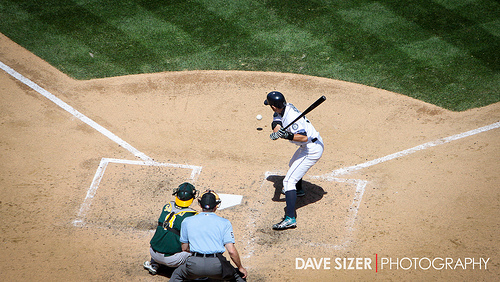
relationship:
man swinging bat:
[264, 89, 327, 231] [270, 96, 328, 139]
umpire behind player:
[168, 187, 249, 281] [143, 183, 199, 276]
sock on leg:
[285, 188, 299, 218] [282, 143, 324, 217]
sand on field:
[2, 30, 500, 281] [0, 0, 499, 281]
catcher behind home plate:
[143, 183, 199, 276] [216, 193, 243, 213]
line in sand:
[0, 59, 152, 168] [2, 30, 500, 281]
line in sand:
[319, 121, 499, 180] [2, 30, 500, 281]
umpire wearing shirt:
[168, 187, 249, 281] [179, 210, 236, 254]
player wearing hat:
[143, 183, 199, 276] [175, 183, 195, 207]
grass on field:
[0, 0, 499, 112] [0, 0, 499, 281]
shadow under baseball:
[256, 127, 266, 132] [256, 114, 263, 121]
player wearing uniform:
[143, 183, 199, 276] [151, 200, 194, 266]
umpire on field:
[168, 187, 249, 281] [0, 0, 499, 281]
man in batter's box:
[264, 89, 327, 231] [73, 156, 368, 259]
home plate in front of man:
[216, 193, 243, 213] [264, 89, 327, 231]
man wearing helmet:
[264, 89, 327, 231] [263, 90, 286, 107]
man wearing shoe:
[264, 89, 327, 231] [272, 215, 298, 231]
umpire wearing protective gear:
[168, 187, 249, 281] [198, 189, 221, 208]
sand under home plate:
[2, 30, 500, 281] [216, 193, 243, 213]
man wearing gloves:
[264, 89, 327, 231] [270, 128, 290, 142]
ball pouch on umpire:
[215, 253, 237, 279] [168, 187, 249, 281]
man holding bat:
[264, 89, 327, 231] [270, 96, 328, 139]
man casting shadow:
[264, 89, 327, 231] [266, 175, 328, 211]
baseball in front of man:
[256, 114, 263, 121] [264, 89, 327, 231]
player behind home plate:
[143, 183, 199, 276] [216, 193, 243, 213]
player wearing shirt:
[143, 183, 199, 276] [151, 203, 192, 253]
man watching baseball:
[264, 89, 327, 231] [256, 114, 263, 121]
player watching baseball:
[143, 183, 199, 276] [256, 114, 263, 121]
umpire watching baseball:
[168, 187, 249, 281] [256, 114, 263, 121]